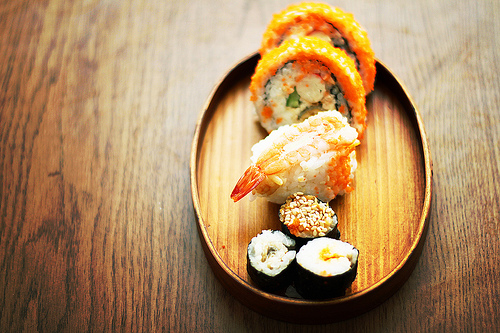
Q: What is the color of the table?
A: Brown.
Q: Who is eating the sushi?
A: No one.